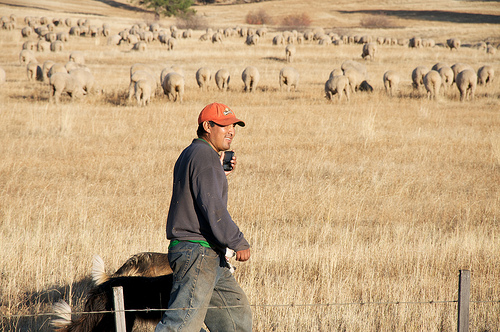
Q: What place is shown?
A: It is a field.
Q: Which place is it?
A: It is a field.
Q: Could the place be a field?
A: Yes, it is a field.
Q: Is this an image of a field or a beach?
A: It is showing a field.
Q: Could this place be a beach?
A: No, it is a field.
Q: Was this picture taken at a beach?
A: No, the picture was taken in a field.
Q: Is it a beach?
A: No, it is a field.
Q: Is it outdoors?
A: Yes, it is outdoors.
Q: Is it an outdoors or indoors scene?
A: It is outdoors.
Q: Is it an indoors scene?
A: No, it is outdoors.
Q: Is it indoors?
A: No, it is outdoors.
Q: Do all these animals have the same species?
A: No, there are both sheep and elephants.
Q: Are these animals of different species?
A: Yes, they are sheep and elephants.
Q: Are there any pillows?
A: No, there are no pillows.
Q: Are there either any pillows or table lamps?
A: No, there are no pillows or table lamps.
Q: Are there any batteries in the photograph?
A: No, there are no batteries.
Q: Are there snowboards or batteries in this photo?
A: No, there are no batteries or snowboards.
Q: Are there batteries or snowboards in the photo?
A: No, there are no batteries or snowboards.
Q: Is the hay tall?
A: Yes, the hay is tall.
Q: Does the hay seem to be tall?
A: Yes, the hay is tall.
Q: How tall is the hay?
A: The hay is tall.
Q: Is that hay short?
A: No, the hay is tall.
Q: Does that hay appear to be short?
A: No, the hay is tall.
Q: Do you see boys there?
A: No, there are no boys.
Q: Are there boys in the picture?
A: No, there are no boys.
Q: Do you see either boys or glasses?
A: No, there are no boys or glasses.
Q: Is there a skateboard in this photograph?
A: No, there are no skateboards.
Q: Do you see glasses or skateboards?
A: No, there are no skateboards or glasses.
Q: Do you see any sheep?
A: Yes, there is a sheep.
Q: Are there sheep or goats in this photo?
A: Yes, there is a sheep.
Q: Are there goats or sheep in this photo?
A: Yes, there is a sheep.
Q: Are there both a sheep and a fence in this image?
A: Yes, there are both a sheep and a fence.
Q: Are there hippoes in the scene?
A: No, there are no hippoes.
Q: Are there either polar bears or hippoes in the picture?
A: No, there are no hippoes or polar bears.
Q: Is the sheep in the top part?
A: Yes, the sheep is in the top of the image.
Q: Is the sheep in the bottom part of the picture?
A: No, the sheep is in the top of the image.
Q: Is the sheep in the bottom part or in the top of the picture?
A: The sheep is in the top of the image.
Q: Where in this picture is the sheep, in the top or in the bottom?
A: The sheep is in the top of the image.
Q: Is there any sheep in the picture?
A: Yes, there is a sheep.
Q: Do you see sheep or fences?
A: Yes, there is a sheep.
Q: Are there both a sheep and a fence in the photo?
A: Yes, there are both a sheep and a fence.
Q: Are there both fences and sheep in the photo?
A: Yes, there are both a sheep and a fence.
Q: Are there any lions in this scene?
A: No, there are no lions.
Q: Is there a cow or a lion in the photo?
A: No, there are no lions or cows.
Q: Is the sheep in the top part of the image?
A: Yes, the sheep is in the top of the image.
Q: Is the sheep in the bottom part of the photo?
A: No, the sheep is in the top of the image.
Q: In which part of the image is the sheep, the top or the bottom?
A: The sheep is in the top of the image.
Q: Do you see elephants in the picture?
A: Yes, there are elephants.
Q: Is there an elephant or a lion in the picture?
A: Yes, there are elephants.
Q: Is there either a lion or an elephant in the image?
A: Yes, there are elephants.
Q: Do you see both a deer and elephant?
A: No, there are elephants but no deer.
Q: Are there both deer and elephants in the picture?
A: No, there are elephants but no deer.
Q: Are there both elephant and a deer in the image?
A: No, there are elephants but no deer.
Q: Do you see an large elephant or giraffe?
A: Yes, there are large elephants.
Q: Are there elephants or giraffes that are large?
A: Yes, the elephants are large.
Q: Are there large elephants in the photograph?
A: Yes, there are large elephants.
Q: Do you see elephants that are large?
A: Yes, there are elephants that are large.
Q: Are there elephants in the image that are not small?
A: Yes, there are large elephants.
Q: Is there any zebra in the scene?
A: No, there are no zebras.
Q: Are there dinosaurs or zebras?
A: No, there are no zebras or dinosaurs.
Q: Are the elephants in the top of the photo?
A: Yes, the elephants are in the top of the image.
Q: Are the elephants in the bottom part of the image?
A: No, the elephants are in the top of the image.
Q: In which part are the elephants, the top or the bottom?
A: The elephants are in the top of the image.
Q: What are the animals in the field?
A: The animals are elephants.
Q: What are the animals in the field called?
A: The animals are elephants.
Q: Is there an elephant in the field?
A: Yes, there are elephants in the field.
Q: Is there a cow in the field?
A: No, there are elephants in the field.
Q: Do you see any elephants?
A: Yes, there are elephants.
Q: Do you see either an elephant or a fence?
A: Yes, there are elephants.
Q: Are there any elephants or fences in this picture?
A: Yes, there are elephants.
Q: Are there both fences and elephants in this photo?
A: Yes, there are both elephants and a fence.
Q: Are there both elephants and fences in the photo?
A: Yes, there are both elephants and a fence.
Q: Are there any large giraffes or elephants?
A: Yes, there are large elephants.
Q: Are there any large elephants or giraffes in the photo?
A: Yes, there are large elephants.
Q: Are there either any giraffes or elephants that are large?
A: Yes, the elephants are large.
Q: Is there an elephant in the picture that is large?
A: Yes, there are large elephants.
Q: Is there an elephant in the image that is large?
A: Yes, there are elephants that are large.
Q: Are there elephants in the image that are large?
A: Yes, there are elephants that are large.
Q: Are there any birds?
A: No, there are no birds.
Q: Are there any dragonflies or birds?
A: No, there are no birds or dragonflies.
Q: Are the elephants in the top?
A: Yes, the elephants are in the top of the image.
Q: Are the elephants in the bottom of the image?
A: No, the elephants are in the top of the image.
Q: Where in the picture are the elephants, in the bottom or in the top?
A: The elephants are in the top of the image.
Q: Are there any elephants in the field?
A: Yes, there are elephants in the field.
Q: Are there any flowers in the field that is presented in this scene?
A: No, there are elephants in the field.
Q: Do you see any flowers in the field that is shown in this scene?
A: No, there are elephants in the field.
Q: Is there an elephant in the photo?
A: Yes, there are elephants.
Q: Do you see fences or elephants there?
A: Yes, there are elephants.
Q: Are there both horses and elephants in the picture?
A: No, there are elephants but no horses.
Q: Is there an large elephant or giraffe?
A: Yes, there are large elephants.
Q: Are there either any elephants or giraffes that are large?
A: Yes, the elephants are large.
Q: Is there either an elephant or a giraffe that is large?
A: Yes, the elephants are large.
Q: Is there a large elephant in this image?
A: Yes, there are large elephants.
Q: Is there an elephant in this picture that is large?
A: Yes, there are elephants that are large.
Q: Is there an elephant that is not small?
A: Yes, there are large elephants.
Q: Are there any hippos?
A: No, there are no hippos.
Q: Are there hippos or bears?
A: No, there are no hippos or bears.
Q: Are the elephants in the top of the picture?
A: Yes, the elephants are in the top of the image.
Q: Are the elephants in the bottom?
A: No, the elephants are in the top of the image.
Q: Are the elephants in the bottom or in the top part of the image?
A: The elephants are in the top of the image.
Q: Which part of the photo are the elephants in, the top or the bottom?
A: The elephants are in the top of the image.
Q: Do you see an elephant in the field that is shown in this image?
A: Yes, there are elephants in the field.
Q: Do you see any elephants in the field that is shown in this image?
A: Yes, there are elephants in the field.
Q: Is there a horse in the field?
A: No, there are elephants in the field.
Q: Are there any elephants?
A: Yes, there are elephants.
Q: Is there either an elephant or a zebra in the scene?
A: Yes, there are elephants.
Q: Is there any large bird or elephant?
A: Yes, there are large elephants.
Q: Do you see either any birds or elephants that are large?
A: Yes, the elephants are large.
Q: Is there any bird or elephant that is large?
A: Yes, the elephants are large.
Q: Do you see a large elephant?
A: Yes, there are large elephants.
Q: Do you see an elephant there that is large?
A: Yes, there are elephants that are large.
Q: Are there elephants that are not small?
A: Yes, there are large elephants.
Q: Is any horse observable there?
A: No, there are no horses.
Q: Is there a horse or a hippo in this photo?
A: No, there are no horses or hippos.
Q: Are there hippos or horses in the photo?
A: No, there are no horses or hippos.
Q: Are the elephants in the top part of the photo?
A: Yes, the elephants are in the top of the image.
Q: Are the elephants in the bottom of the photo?
A: No, the elephants are in the top of the image.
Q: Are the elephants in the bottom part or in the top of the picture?
A: The elephants are in the top of the image.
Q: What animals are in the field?
A: The animals are elephants.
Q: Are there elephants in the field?
A: Yes, there are elephants in the field.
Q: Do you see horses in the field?
A: No, there are elephants in the field.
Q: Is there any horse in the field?
A: No, there are elephants in the field.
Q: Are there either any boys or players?
A: No, there are no players or boys.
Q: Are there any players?
A: No, there are no players.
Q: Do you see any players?
A: No, there are no players.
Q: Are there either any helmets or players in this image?
A: No, there are no players or helmets.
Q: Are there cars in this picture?
A: No, there are no cars.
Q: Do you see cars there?
A: No, there are no cars.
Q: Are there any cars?
A: No, there are no cars.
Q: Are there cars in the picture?
A: No, there are no cars.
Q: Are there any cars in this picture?
A: No, there are no cars.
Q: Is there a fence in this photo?
A: Yes, there is a fence.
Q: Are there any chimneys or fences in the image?
A: Yes, there is a fence.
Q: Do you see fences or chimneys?
A: Yes, there is a fence.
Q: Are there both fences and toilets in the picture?
A: No, there is a fence but no toilets.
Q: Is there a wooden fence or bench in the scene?
A: Yes, there is a wood fence.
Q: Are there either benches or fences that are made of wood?
A: Yes, the fence is made of wood.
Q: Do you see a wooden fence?
A: Yes, there is a wood fence.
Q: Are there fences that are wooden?
A: Yes, there is a fence that is wooden.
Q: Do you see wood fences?
A: Yes, there is a fence that is made of wood.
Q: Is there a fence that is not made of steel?
A: Yes, there is a fence that is made of wood.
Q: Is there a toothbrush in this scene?
A: No, there are no toothbrushes.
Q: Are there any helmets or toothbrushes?
A: No, there are no toothbrushes or helmets.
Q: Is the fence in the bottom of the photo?
A: Yes, the fence is in the bottom of the image.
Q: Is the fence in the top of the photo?
A: No, the fence is in the bottom of the image.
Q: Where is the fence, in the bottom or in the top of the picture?
A: The fence is in the bottom of the image.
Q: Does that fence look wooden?
A: Yes, the fence is wooden.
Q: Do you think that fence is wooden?
A: Yes, the fence is wooden.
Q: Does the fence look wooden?
A: Yes, the fence is wooden.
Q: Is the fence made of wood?
A: Yes, the fence is made of wood.